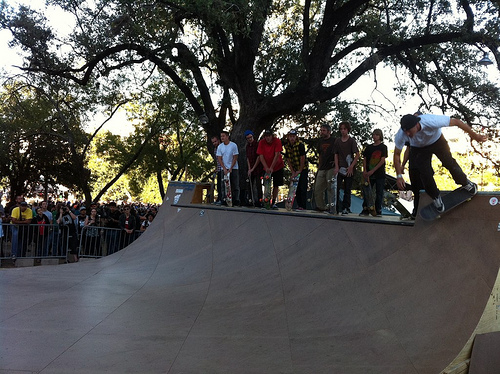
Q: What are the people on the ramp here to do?
A: Skateboard.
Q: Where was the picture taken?
A: Skate park.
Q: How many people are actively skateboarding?
A: One.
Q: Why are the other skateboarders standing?
A: Waiting for their turn.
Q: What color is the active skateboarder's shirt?
A: White.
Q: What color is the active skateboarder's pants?
A: Black.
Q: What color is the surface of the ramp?
A: Brown.